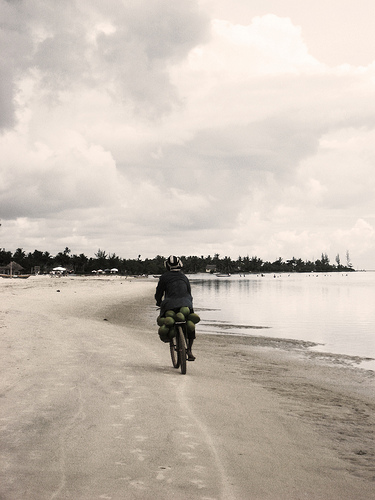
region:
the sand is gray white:
[155, 435, 178, 454]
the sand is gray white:
[160, 437, 179, 467]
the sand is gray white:
[162, 430, 174, 447]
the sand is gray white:
[172, 461, 185, 478]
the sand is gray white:
[170, 471, 197, 495]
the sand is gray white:
[162, 460, 205, 494]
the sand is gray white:
[179, 458, 184, 471]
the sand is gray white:
[184, 477, 196, 490]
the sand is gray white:
[182, 462, 207, 496]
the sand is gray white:
[171, 465, 195, 486]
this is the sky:
[100, 16, 318, 125]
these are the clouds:
[213, 41, 291, 87]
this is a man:
[153, 253, 196, 308]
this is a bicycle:
[174, 328, 193, 364]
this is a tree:
[96, 246, 105, 267]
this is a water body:
[275, 270, 365, 308]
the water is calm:
[292, 277, 340, 302]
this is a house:
[1, 259, 16, 270]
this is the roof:
[6, 260, 14, 263]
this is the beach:
[155, 405, 360, 457]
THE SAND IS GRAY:
[149, 439, 171, 460]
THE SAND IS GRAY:
[205, 462, 220, 477]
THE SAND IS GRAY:
[194, 464, 213, 492]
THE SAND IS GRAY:
[205, 466, 234, 490]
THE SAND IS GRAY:
[185, 471, 211, 495]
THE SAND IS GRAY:
[189, 478, 217, 498]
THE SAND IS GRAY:
[196, 482, 212, 494]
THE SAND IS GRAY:
[200, 473, 220, 485]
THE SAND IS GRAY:
[232, 473, 244, 492]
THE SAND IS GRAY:
[221, 465, 234, 488]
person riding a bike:
[142, 245, 211, 381]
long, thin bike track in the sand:
[172, 374, 234, 495]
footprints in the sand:
[95, 366, 179, 496]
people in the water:
[256, 270, 356, 280]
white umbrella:
[49, 262, 69, 275]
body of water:
[190, 270, 374, 368]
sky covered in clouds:
[1, 0, 374, 265]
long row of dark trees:
[3, 242, 353, 272]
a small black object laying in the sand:
[56, 287, 62, 292]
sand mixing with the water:
[266, 330, 334, 355]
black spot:
[160, 462, 171, 477]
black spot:
[157, 464, 167, 472]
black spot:
[163, 460, 167, 477]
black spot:
[155, 462, 168, 479]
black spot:
[158, 464, 174, 481]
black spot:
[157, 462, 175, 469]